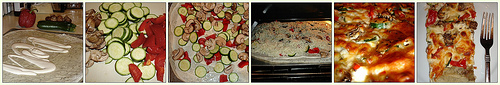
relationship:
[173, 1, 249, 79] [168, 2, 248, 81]
veggies on sauce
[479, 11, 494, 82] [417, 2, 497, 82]
fork on table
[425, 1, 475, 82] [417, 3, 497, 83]
dinner on plate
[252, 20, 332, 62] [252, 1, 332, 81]
pizza baking in oven